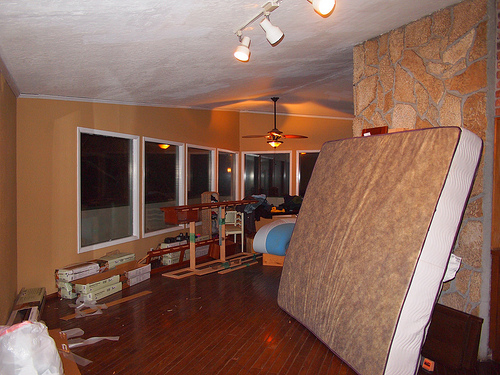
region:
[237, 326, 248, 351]
the floor is wooden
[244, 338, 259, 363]
the floor is wooden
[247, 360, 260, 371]
the floor is wooden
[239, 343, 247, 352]
the floor is wooden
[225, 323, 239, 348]
the floor is wooden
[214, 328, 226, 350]
the floor is wooden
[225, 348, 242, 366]
the floor is wooden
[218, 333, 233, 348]
the floor is wooden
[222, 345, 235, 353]
the floor is wooden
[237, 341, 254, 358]
the floor is wooden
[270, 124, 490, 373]
a mattress leaning against a wall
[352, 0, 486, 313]
a stone wall in a room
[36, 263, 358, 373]
a hardwood floor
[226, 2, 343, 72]
white track lights on a ceiling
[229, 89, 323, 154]
a ceiling fan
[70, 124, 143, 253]
a window in a room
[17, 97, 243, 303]
an orange painted wall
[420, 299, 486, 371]
a wood bed frame behind a mattress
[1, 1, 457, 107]
a white ceiling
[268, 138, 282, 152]
a light in a ceiling fan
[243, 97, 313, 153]
A ceiling fan with a light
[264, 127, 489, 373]
a mattress leaning against the wall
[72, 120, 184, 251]
Windows with white trim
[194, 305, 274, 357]
brown parkay floors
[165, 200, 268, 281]
wooden bed frames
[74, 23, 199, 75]
white ceiling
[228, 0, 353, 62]
white ceiling track lights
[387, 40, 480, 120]
a stone colored wall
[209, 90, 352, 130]
light shadow cast on the wall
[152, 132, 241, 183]
reflection of light on the windows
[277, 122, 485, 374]
Mattress leaning against a wall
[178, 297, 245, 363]
Natural wood flooring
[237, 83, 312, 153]
Ceiling fan mounted to ceiling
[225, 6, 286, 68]
Overhead lighting mounted ceiling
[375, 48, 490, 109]
Wall made of stone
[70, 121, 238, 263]
Row of large windows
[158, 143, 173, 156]
Reflection of ceiling fan light in the window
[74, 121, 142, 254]
White window frame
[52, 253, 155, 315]
Packages of natural wood flooring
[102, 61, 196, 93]
Textured stucco ceiling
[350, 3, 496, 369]
stone wall with stuff leaning on it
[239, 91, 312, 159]
ceiling fan with light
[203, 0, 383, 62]
track lights hanging from ceiling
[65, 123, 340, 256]
windows with white sills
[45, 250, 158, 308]
wood flooring supplies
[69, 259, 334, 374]
wood floors laid out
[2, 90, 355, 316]
tan walls of room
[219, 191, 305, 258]
pile of stuff stacked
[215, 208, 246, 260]
white chair in pile of stuff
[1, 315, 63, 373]
white bag filled with stuff